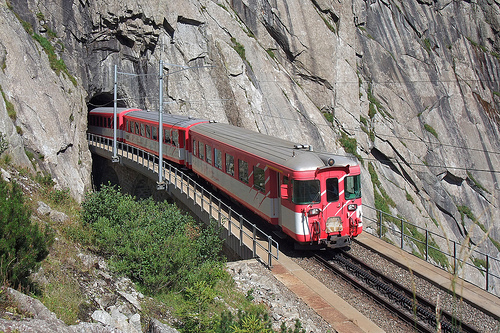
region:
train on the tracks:
[82, 96, 392, 269]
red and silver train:
[87, 99, 374, 264]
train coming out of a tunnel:
[73, 80, 380, 279]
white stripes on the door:
[322, 168, 349, 240]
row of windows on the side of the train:
[187, 138, 270, 198]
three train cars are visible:
[79, 90, 397, 272]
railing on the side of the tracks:
[87, 136, 282, 274]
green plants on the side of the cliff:
[332, 118, 499, 261]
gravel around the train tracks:
[298, 239, 491, 331]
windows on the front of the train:
[291, 170, 361, 207]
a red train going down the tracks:
[91, 82, 383, 276]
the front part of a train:
[285, 139, 377, 259]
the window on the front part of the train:
[277, 176, 329, 208]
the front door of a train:
[311, 168, 343, 246]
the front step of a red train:
[317, 226, 365, 253]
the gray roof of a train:
[272, 133, 329, 180]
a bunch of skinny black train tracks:
[351, 242, 413, 327]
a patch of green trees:
[107, 198, 202, 300]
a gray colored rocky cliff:
[308, 19, 439, 147]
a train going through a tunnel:
[79, 74, 379, 256]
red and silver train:
[81, 102, 366, 256]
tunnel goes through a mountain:
[21, 15, 210, 172]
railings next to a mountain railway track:
[83, 130, 283, 278]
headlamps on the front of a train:
[304, 199, 360, 216]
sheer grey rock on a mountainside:
[0, 1, 498, 286]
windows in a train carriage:
[188, 137, 267, 195]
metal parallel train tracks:
[313, 243, 488, 331]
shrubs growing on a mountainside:
[1, 167, 237, 309]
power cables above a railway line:
[106, 45, 497, 207]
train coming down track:
[83, 98, 365, 246]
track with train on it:
[316, 252, 457, 330]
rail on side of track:
[374, 203, 499, 271]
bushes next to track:
[77, 189, 212, 269]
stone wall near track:
[3, 1, 498, 240]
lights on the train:
[305, 204, 364, 217]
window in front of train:
[344, 176, 364, 197]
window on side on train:
[248, 167, 264, 192]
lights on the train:
[306, 203, 361, 210]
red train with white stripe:
[87, 103, 360, 258]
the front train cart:
[187, 122, 362, 244]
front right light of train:
[307, 205, 321, 219]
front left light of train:
[347, 205, 357, 215]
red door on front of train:
[316, 165, 348, 235]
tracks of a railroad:
[310, 244, 480, 331]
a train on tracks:
[86, 100, 363, 254]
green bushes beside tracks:
[87, 183, 225, 303]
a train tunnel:
[83, 78, 128, 145]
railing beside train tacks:
[359, 203, 499, 293]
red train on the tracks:
[181, 108, 381, 253]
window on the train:
[292, 177, 324, 206]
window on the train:
[245, 164, 267, 198]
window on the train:
[219, 152, 238, 182]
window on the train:
[158, 122, 178, 149]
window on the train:
[338, 175, 360, 198]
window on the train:
[132, 120, 159, 140]